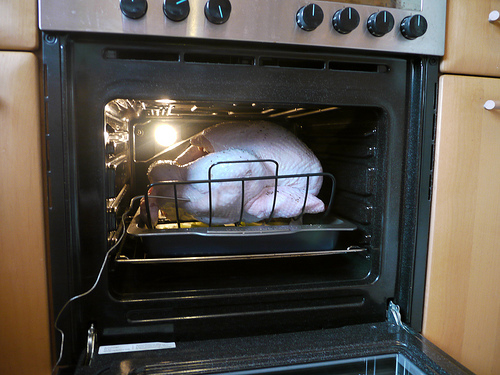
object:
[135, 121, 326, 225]
turkey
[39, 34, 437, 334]
oven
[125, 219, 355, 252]
pan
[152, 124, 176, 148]
light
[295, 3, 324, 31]
knob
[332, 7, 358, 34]
knob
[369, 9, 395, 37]
knob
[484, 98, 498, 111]
knob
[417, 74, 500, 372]
cabinet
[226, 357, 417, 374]
window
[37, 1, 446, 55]
control panel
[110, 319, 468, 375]
door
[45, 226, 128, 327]
cord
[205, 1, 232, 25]
knob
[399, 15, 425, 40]
knob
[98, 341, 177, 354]
sticker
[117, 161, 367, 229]
rack